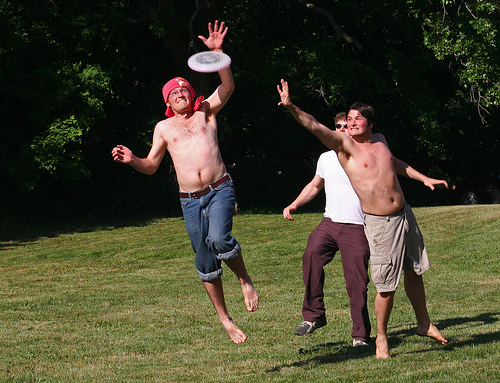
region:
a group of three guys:
[98, 7, 460, 370]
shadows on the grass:
[266, 312, 498, 371]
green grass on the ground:
[5, 203, 499, 381]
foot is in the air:
[286, 311, 333, 343]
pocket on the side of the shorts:
[367, 253, 396, 290]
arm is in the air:
[268, 74, 356, 154]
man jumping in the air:
[105, 21, 287, 363]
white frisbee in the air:
[178, 49, 240, 76]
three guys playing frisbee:
[103, 18, 466, 372]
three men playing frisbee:
[112, 17, 459, 363]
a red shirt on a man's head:
[158, 75, 208, 120]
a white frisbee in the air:
[184, 48, 234, 77]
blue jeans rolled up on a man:
[181, 176, 239, 289]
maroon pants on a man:
[298, 218, 373, 341]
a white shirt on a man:
[314, 148, 368, 224]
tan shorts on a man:
[358, 201, 433, 292]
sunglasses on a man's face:
[333, 120, 350, 134]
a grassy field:
[4, 202, 498, 381]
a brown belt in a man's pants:
[178, 171, 231, 200]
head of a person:
[147, 76, 201, 126]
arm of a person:
[116, 131, 190, 179]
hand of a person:
[100, 133, 137, 167]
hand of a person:
[196, 13, 246, 50]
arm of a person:
[202, 65, 247, 109]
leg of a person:
[209, 195, 243, 276]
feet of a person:
[227, 276, 267, 306]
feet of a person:
[209, 326, 253, 353]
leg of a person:
[287, 312, 335, 340]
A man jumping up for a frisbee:
[109, 19, 274, 356]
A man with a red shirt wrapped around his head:
[93, 13, 271, 345]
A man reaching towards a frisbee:
[263, 63, 455, 358]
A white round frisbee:
[180, 47, 229, 79]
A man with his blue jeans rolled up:
[119, 33, 267, 358]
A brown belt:
[164, 173, 231, 200]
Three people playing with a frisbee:
[100, 35, 468, 357]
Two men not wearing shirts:
[94, 17, 449, 357]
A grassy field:
[0, 193, 493, 380]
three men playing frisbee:
[110, 18, 455, 359]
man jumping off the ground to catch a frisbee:
[111, 19, 259, 344]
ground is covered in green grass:
[3, 203, 499, 378]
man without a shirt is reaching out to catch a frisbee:
[274, 76, 449, 361]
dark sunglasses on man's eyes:
[333, 121, 350, 129]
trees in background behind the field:
[0, 1, 495, 203]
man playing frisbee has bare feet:
[108, 18, 258, 343]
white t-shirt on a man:
[313, 146, 361, 223]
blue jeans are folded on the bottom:
[172, 173, 240, 279]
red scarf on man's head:
[161, 75, 203, 116]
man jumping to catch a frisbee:
[119, 15, 271, 350]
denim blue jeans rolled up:
[170, 166, 262, 353]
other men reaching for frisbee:
[266, 70, 453, 381]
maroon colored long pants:
[293, 211, 388, 362]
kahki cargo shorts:
[354, 193, 439, 298]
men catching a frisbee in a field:
[74, 10, 471, 380]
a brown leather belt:
[171, 175, 243, 202]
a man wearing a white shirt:
[315, 149, 358, 221]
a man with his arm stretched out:
[272, 76, 364, 163]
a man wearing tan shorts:
[362, 201, 428, 300]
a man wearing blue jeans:
[180, 184, 236, 278]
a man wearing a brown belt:
[175, 170, 233, 203]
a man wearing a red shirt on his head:
[162, 75, 197, 119]